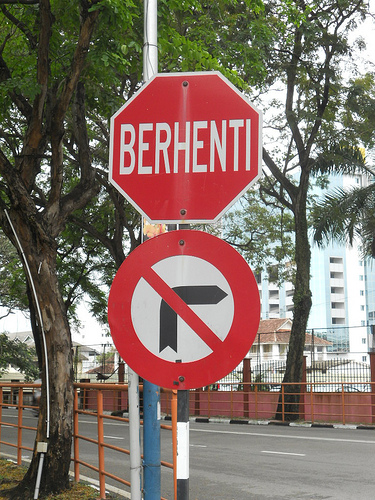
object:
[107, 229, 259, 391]
sign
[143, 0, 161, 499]
pole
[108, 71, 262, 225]
sign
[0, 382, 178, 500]
fence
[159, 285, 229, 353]
arrow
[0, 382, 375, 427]
curb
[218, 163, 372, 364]
building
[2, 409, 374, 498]
road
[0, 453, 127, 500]
grass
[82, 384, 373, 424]
wall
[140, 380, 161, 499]
pole section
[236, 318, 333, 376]
house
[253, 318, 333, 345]
roof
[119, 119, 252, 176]
behrenti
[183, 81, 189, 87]
screw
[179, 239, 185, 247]
screw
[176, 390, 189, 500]
pole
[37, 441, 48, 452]
electrical box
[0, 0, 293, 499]
tree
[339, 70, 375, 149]
leaves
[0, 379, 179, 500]
gate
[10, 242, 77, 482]
trunk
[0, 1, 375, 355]
clouds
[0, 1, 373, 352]
sky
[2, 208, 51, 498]
wire